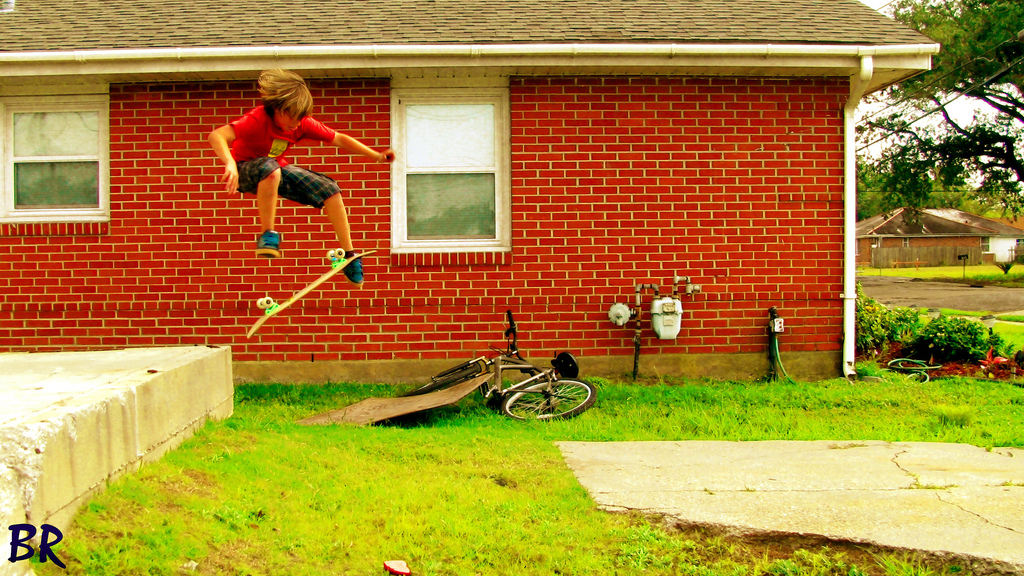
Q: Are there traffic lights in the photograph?
A: No, there are no traffic lights.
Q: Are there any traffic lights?
A: No, there are no traffic lights.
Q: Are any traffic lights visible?
A: No, there are no traffic lights.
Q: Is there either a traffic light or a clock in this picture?
A: No, there are no traffic lights or clocks.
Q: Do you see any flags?
A: No, there are no flags.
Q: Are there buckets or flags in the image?
A: No, there are no flags or buckets.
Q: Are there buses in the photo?
A: No, there are no buses.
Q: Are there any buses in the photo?
A: No, there are no buses.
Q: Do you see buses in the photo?
A: No, there are no buses.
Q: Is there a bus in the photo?
A: No, there are no buses.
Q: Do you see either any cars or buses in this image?
A: No, there are no buses or cars.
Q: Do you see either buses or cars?
A: No, there are no buses or cars.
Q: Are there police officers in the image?
A: No, there are no police officers.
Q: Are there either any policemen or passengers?
A: No, there are no policemen or passengers.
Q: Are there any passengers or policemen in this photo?
A: No, there are no policemen or passengers.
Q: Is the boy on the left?
A: Yes, the boy is on the left of the image.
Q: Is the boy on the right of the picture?
A: No, the boy is on the left of the image.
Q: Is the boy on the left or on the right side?
A: The boy is on the left of the image.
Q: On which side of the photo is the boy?
A: The boy is on the left of the image.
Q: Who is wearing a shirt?
A: The boy is wearing a shirt.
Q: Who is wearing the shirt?
A: The boy is wearing a shirt.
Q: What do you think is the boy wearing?
A: The boy is wearing a shirt.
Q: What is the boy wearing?
A: The boy is wearing a shirt.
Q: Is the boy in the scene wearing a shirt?
A: Yes, the boy is wearing a shirt.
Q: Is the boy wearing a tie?
A: No, the boy is wearing a shirt.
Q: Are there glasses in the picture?
A: No, there are no glasses.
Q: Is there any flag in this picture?
A: No, there are no flags.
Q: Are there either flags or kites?
A: No, there are no flags or kites.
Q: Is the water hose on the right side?
A: Yes, the water hose is on the right of the image.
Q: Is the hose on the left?
A: No, the hose is on the right of the image.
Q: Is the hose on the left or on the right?
A: The hose is on the right of the image.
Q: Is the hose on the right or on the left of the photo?
A: The hose is on the right of the image.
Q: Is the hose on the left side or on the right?
A: The hose is on the right of the image.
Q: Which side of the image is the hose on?
A: The hose is on the right of the image.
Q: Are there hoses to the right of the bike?
A: Yes, there is a hose to the right of the bike.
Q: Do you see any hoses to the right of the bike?
A: Yes, there is a hose to the right of the bike.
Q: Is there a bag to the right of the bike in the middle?
A: No, there is a hose to the right of the bike.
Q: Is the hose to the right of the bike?
A: Yes, the hose is to the right of the bike.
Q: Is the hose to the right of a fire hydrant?
A: No, the hose is to the right of the bike.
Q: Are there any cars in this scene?
A: No, there are no cars.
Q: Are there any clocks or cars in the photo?
A: No, there are no cars or clocks.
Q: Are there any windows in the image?
A: Yes, there is a window.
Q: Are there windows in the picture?
A: Yes, there is a window.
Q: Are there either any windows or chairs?
A: Yes, there is a window.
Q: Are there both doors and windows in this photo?
A: No, there is a window but no doors.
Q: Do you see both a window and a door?
A: No, there is a window but no doors.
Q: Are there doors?
A: No, there are no doors.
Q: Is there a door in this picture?
A: No, there are no doors.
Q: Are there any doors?
A: No, there are no doors.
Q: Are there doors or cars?
A: No, there are no doors or cars.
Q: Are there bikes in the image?
A: Yes, there is a bike.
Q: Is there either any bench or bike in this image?
A: Yes, there is a bike.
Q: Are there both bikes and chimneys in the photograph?
A: No, there is a bike but no chimneys.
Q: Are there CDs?
A: No, there are no cds.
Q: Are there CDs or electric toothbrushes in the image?
A: No, there are no CDs or electric toothbrushes.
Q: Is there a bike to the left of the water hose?
A: Yes, there is a bike to the left of the water hose.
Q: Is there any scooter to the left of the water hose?
A: No, there is a bike to the left of the water hose.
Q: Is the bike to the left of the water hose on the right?
A: Yes, the bike is to the left of the water hose.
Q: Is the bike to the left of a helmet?
A: No, the bike is to the left of the water hose.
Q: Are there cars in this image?
A: No, there are no cars.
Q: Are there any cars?
A: No, there are no cars.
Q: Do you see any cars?
A: No, there are no cars.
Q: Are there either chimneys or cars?
A: No, there are no cars or chimneys.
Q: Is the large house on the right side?
A: Yes, the house is on the right of the image.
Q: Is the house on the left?
A: No, the house is on the right of the image.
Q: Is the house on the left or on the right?
A: The house is on the right of the image.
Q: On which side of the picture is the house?
A: The house is on the right of the image.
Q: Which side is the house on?
A: The house is on the right of the image.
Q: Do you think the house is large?
A: Yes, the house is large.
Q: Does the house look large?
A: Yes, the house is large.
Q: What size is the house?
A: The house is large.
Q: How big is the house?
A: The house is large.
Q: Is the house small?
A: No, the house is large.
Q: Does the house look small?
A: No, the house is large.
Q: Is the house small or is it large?
A: The house is large.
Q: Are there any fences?
A: Yes, there is a fence.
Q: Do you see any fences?
A: Yes, there is a fence.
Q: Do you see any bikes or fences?
A: Yes, there is a fence.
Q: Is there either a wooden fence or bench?
A: Yes, there is a wood fence.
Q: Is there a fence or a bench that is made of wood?
A: Yes, the fence is made of wood.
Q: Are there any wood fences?
A: Yes, there is a wood fence.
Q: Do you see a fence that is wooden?
A: Yes, there is a fence that is wooden.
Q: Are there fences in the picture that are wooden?
A: Yes, there is a fence that is wooden.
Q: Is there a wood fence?
A: Yes, there is a fence that is made of wood.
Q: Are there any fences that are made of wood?
A: Yes, there is a fence that is made of wood.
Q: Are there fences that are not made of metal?
A: Yes, there is a fence that is made of wood.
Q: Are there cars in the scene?
A: No, there are no cars.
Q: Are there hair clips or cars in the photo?
A: No, there are no cars or hair clips.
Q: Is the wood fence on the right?
A: Yes, the fence is on the right of the image.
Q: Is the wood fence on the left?
A: No, the fence is on the right of the image.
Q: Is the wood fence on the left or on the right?
A: The fence is on the right of the image.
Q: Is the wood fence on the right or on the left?
A: The fence is on the right of the image.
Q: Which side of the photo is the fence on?
A: The fence is on the right of the image.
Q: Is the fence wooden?
A: Yes, the fence is wooden.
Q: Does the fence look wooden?
A: Yes, the fence is wooden.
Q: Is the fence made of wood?
A: Yes, the fence is made of wood.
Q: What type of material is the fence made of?
A: The fence is made of wood.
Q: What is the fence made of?
A: The fence is made of wood.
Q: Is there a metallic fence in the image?
A: No, there is a fence but it is wooden.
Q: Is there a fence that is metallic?
A: No, there is a fence but it is wooden.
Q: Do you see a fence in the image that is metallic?
A: No, there is a fence but it is wooden.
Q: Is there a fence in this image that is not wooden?
A: No, there is a fence but it is wooden.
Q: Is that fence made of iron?
A: No, the fence is made of wood.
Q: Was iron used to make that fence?
A: No, the fence is made of wood.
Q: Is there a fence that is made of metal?
A: No, there is a fence but it is made of wood.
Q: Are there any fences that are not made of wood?
A: No, there is a fence but it is made of wood.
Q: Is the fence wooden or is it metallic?
A: The fence is wooden.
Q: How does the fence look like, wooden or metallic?
A: The fence is wooden.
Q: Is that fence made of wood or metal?
A: The fence is made of wood.